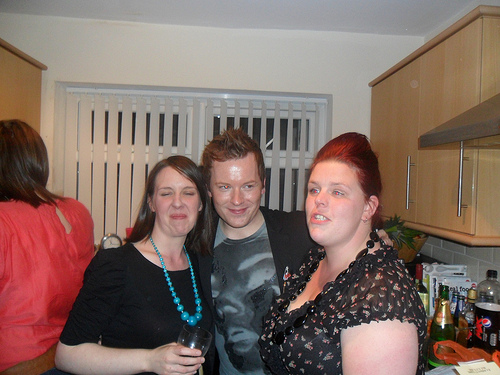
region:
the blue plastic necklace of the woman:
[145, 227, 210, 323]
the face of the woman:
[154, 168, 192, 232]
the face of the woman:
[305, 159, 380, 246]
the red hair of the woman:
[317, 132, 381, 199]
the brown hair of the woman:
[131, 148, 209, 248]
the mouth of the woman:
[167, 209, 191, 221]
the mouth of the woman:
[309, 211, 330, 222]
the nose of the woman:
[172, 194, 182, 207]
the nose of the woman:
[312, 185, 327, 205]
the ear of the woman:
[144, 193, 157, 210]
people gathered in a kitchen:
[5, 57, 481, 372]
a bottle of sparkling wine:
[423, 279, 458, 366]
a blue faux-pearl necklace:
[144, 233, 212, 328]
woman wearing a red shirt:
[0, 200, 90, 358]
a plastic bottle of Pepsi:
[465, 270, 498, 348]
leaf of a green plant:
[381, 212, 429, 254]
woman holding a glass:
[163, 317, 218, 374]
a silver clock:
[94, 228, 126, 250]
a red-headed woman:
[300, 125, 389, 247]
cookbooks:
[423, 259, 498, 294]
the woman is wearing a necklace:
[142, 209, 234, 346]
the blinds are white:
[61, 98, 325, 253]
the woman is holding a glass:
[74, 212, 221, 372]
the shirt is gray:
[210, 230, 240, 360]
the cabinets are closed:
[342, 56, 499, 291]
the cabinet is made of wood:
[368, 73, 493, 278]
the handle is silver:
[425, 115, 471, 247]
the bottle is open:
[423, 255, 488, 360]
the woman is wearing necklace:
[108, 138, 233, 371]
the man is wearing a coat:
[173, 181, 390, 371]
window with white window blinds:
[55, 77, 335, 279]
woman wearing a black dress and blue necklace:
[60, 152, 207, 373]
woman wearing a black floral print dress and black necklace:
[263, 132, 425, 374]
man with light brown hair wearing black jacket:
[205, 127, 300, 373]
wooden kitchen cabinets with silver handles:
[377, 1, 498, 245]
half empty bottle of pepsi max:
[474, 267, 499, 349]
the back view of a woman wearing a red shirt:
[1, 117, 89, 352]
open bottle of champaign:
[424, 284, 456, 369]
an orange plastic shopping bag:
[429, 340, 498, 368]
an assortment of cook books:
[426, 258, 478, 323]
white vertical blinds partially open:
[49, 85, 330, 258]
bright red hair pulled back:
[303, 130, 388, 249]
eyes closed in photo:
[130, 150, 212, 334]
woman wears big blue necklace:
[143, 228, 207, 327]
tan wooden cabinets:
[366, 5, 498, 244]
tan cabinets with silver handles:
[363, 5, 498, 239]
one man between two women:
[48, 126, 428, 373]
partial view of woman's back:
[0, 115, 100, 373]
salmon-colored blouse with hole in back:
[5, 191, 95, 363]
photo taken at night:
[58, 92, 314, 243]